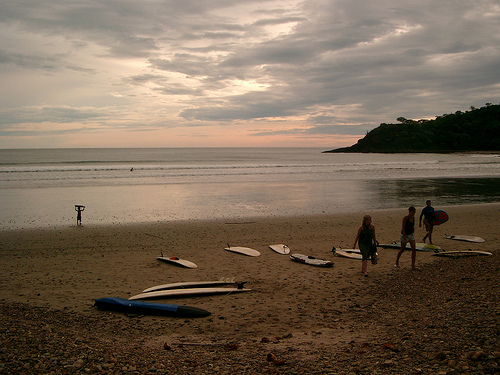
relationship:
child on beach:
[73, 207, 83, 226] [1, 147, 498, 373]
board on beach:
[156, 254, 198, 268] [33, 244, 103, 291]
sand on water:
[0, 204, 500, 373] [0, 145, 500, 235]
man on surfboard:
[419, 200, 435, 245] [423, 195, 455, 230]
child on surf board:
[75, 207, 85, 226] [67, 192, 86, 210]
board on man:
[294, 235, 396, 323] [352, 214, 377, 276]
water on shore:
[5, 150, 496, 231] [122, 167, 333, 235]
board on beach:
[156, 254, 198, 268] [0, 203, 498, 374]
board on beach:
[223, 246, 262, 257] [0, 203, 498, 374]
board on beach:
[268, 243, 291, 255] [0, 203, 498, 374]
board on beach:
[156, 254, 198, 268] [27, 209, 354, 347]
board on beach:
[223, 246, 262, 257] [27, 209, 354, 347]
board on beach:
[289, 253, 334, 266] [27, 209, 354, 347]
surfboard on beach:
[438, 240, 488, 257] [27, 209, 354, 347]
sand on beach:
[0, 204, 500, 373] [25, 196, 369, 331]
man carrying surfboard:
[419, 200, 435, 245] [423, 210, 449, 226]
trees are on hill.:
[321, 99, 498, 154] [320, 99, 499, 151]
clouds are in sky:
[172, 48, 297, 109] [1, 1, 490, 147]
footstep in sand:
[318, 283, 330, 293] [0, 204, 500, 373]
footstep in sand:
[335, 273, 343, 282] [0, 204, 500, 373]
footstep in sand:
[300, 285, 310, 295] [0, 204, 500, 373]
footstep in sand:
[303, 297, 314, 307] [0, 204, 500, 373]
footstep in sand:
[284, 306, 294, 313] [0, 204, 500, 373]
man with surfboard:
[419, 200, 435, 245] [416, 210, 449, 227]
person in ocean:
[128, 163, 132, 175] [5, 142, 483, 248]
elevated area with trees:
[358, 104, 498, 154] [391, 92, 496, 122]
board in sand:
[158, 254, 197, 270] [2, 187, 483, 359]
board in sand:
[217, 240, 261, 264] [2, 187, 483, 359]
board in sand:
[268, 236, 288, 256] [2, 187, 483, 359]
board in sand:
[295, 249, 335, 273] [2, 187, 483, 359]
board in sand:
[333, 238, 375, 259] [2, 187, 483, 359]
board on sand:
[156, 254, 198, 268] [2, 187, 483, 359]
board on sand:
[223, 246, 262, 257] [2, 187, 483, 359]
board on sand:
[268, 243, 291, 255] [2, 187, 483, 359]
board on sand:
[289, 253, 334, 266] [2, 187, 483, 359]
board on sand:
[330, 246, 379, 260] [2, 187, 483, 359]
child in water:
[75, 207, 85, 226] [33, 180, 498, 216]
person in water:
[130, 167, 134, 171] [33, 180, 498, 216]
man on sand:
[352, 214, 377, 276] [0, 204, 500, 373]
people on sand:
[394, 206, 416, 271] [0, 204, 500, 373]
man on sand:
[419, 200, 435, 245] [0, 204, 500, 373]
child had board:
[75, 207, 85, 226] [69, 199, 89, 210]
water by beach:
[5, 150, 496, 231] [14, 188, 484, 349]